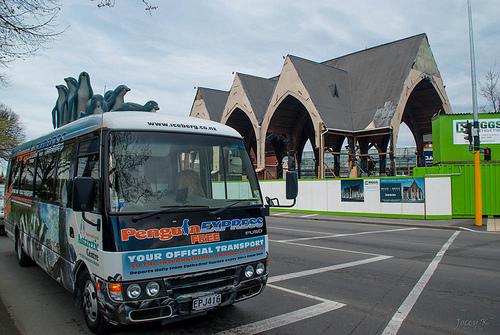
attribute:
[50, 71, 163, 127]
penguins — fake, decorative, blue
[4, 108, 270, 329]
bus — colorful, penguin express, parked, blue, white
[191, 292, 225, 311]
license plate — epj416, white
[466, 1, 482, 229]
pole — painted, metal, tall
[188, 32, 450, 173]
building — large, chapel style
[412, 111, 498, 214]
storage container — green, lime green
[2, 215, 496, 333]
street — paved, grey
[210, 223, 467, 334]
lines — white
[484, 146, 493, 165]
crossing signal — red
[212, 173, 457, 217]
fence — green, white, wooden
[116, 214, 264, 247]
ad — penguin express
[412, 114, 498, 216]
containers — green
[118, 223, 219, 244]
letters — red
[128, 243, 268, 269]
letters — red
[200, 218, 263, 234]
letters — blue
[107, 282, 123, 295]
light — orange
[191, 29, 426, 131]
roof — brown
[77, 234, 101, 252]
letters — green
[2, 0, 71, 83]
tree — bare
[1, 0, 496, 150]
sky — grey, cloudy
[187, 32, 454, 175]
structure — wood, under construction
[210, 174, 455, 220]
barrier — long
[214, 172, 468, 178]
trim — green